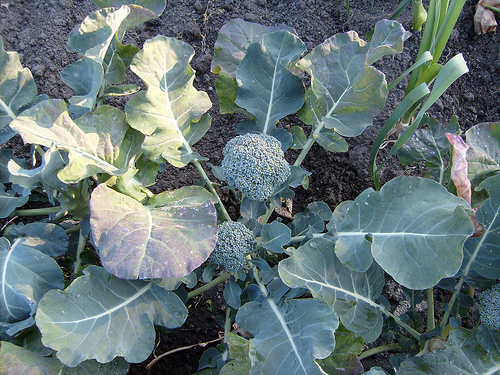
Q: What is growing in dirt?
A: Broccoli plant.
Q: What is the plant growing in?
A: The dirt.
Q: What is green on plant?
A: Leaf.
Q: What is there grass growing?
A: In dirt.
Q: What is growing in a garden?
A: Broccoli.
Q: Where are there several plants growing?
A: In a garden.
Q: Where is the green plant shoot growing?
A: In the garden.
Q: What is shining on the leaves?
A: Sun.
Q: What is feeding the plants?
A: Soil.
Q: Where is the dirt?
A: Ground.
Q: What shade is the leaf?
A: Green.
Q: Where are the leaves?
A: Garden.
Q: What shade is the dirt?
A: Gray.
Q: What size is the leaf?
A: Large.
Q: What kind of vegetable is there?
A: Collard greens.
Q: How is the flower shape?
A: Bulb.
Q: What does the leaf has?
A: Purple color.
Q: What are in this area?
A: Green leaves.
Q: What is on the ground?
A: Dirt.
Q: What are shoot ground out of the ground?
A: Green flower.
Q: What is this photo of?
A: A garden.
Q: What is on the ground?
A: Dirt.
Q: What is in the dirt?
A: Roots.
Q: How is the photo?
A: Clear.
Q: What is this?
A: Vegetables.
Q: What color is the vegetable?
A: Green.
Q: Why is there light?
A: SUN.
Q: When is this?
A: Daytime.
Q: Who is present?
A: No one.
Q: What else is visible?
A: Soil.